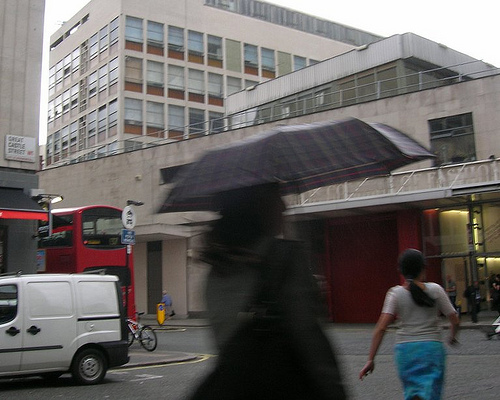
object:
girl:
[358, 248, 462, 399]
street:
[0, 363, 218, 399]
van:
[0, 268, 132, 387]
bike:
[125, 311, 158, 352]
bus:
[35, 204, 138, 334]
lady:
[182, 184, 348, 400]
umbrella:
[149, 115, 438, 298]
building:
[45, 0, 391, 168]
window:
[127, 15, 227, 73]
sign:
[120, 204, 135, 248]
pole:
[119, 198, 137, 342]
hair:
[190, 186, 278, 274]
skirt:
[392, 339, 447, 400]